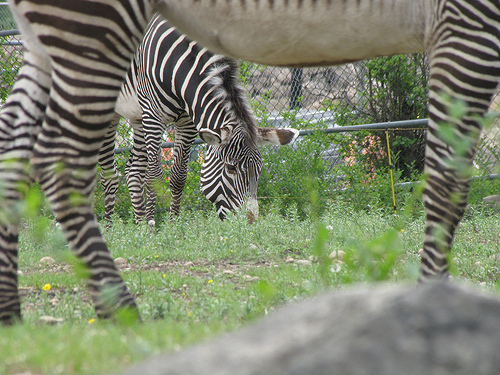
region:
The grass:
[189, 254, 226, 284]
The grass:
[216, 211, 268, 287]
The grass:
[200, 237, 272, 299]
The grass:
[208, 290, 265, 367]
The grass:
[174, 189, 251, 271]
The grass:
[170, 236, 244, 276]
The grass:
[174, 217, 324, 344]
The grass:
[168, 234, 245, 344]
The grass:
[159, 223, 234, 287]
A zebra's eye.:
[220, 156, 254, 190]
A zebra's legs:
[114, 101, 194, 228]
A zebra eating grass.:
[200, 111, 288, 251]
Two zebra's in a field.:
[6, 13, 364, 278]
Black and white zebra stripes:
[412, 20, 498, 285]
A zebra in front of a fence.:
[205, 83, 411, 213]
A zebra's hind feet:
[1, 170, 201, 340]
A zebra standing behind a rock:
[315, 193, 497, 358]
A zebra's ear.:
[187, 106, 242, 152]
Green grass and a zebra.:
[229, 100, 312, 249]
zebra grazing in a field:
[172, 87, 295, 269]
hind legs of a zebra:
[2, 23, 164, 367]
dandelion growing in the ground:
[26, 274, 61, 302]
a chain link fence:
[288, 95, 418, 193]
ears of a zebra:
[190, 118, 310, 156]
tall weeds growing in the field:
[263, 137, 408, 216]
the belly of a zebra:
[140, 2, 463, 80]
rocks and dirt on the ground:
[118, 240, 305, 302]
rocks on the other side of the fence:
[247, 67, 395, 131]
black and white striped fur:
[47, 22, 122, 126]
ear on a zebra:
[254, 123, 303, 148]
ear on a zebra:
[194, 118, 235, 147]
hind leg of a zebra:
[27, 3, 151, 332]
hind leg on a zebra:
[0, 13, 61, 337]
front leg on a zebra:
[410, 0, 498, 330]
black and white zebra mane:
[200, 46, 265, 145]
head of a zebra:
[178, 48, 302, 238]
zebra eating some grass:
[93, 3, 307, 240]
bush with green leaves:
[316, 44, 425, 179]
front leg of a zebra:
[132, 103, 177, 238]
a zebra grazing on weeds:
[107, 28, 307, 242]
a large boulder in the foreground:
[108, 273, 498, 373]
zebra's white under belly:
[134, 0, 424, 70]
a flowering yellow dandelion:
[32, 275, 57, 302]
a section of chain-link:
[258, 67, 420, 189]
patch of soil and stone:
[147, 246, 364, 293]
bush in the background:
[353, 55, 435, 193]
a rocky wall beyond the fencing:
[233, 55, 370, 125]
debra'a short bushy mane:
[212, 28, 254, 133]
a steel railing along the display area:
[305, 110, 430, 149]